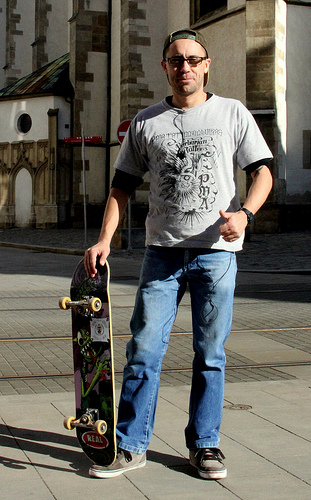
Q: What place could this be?
A: It is a street.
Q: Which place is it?
A: It is a street.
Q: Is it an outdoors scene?
A: Yes, it is outdoors.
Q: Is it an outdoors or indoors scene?
A: It is outdoors.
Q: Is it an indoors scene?
A: No, it is outdoors.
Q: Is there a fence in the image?
A: No, there are no fences.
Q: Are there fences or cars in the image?
A: No, there are no fences or cars.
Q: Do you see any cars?
A: No, there are no cars.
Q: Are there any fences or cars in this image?
A: No, there are no cars or fences.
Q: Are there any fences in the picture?
A: No, there are no fences.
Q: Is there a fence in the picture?
A: No, there are no fences.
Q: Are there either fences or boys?
A: No, there are no fences or boys.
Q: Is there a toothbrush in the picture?
A: No, there are no toothbrushes.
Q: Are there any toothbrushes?
A: No, there are no toothbrushes.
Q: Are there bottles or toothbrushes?
A: No, there are no toothbrushes or bottles.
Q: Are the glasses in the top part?
A: Yes, the glasses are in the top of the image.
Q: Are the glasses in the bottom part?
A: No, the glasses are in the top of the image.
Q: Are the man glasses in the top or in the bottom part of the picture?
A: The glasses are in the top of the image.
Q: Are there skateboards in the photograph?
A: Yes, there is a skateboard.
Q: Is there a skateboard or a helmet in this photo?
A: Yes, there is a skateboard.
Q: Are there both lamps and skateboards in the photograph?
A: No, there is a skateboard but no lamps.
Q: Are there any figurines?
A: No, there are no figurines.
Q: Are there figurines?
A: No, there are no figurines.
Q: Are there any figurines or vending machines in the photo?
A: No, there are no figurines or vending machines.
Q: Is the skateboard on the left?
A: Yes, the skateboard is on the left of the image.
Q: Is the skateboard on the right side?
A: No, the skateboard is on the left of the image.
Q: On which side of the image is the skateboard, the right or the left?
A: The skateboard is on the left of the image.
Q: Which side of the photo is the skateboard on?
A: The skateboard is on the left of the image.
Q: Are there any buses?
A: No, there are no buses.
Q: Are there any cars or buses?
A: No, there are no buses or cars.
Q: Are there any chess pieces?
A: No, there are no chess pieces.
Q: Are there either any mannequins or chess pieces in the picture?
A: No, there are no chess pieces or mannequins.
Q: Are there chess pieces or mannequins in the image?
A: No, there are no chess pieces or mannequins.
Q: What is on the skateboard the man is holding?
A: The sticker is on the skateboard.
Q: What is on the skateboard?
A: The sticker is on the skateboard.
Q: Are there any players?
A: No, there are no players.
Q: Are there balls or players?
A: No, there are no players or balls.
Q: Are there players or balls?
A: No, there are no players or balls.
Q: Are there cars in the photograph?
A: No, there are no cars.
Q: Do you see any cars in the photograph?
A: No, there are no cars.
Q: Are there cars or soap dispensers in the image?
A: No, there are no cars or soap dispensers.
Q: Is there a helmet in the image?
A: No, there are no helmets.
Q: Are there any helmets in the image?
A: No, there are no helmets.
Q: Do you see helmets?
A: No, there are no helmets.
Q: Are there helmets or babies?
A: No, there are no helmets or babies.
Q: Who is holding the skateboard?
A: The man is holding the skateboard.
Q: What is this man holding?
A: The man is holding the skateboard.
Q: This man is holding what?
A: The man is holding the skateboard.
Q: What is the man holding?
A: The man is holding the skateboard.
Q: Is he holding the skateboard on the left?
A: Yes, the man is holding the skateboard.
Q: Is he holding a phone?
A: No, the man is holding the skateboard.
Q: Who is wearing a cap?
A: The man is wearing a cap.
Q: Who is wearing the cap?
A: The man is wearing a cap.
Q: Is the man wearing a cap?
A: Yes, the man is wearing a cap.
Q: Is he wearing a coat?
A: No, the man is wearing a cap.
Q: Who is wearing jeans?
A: The man is wearing jeans.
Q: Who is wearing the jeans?
A: The man is wearing jeans.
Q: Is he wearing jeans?
A: Yes, the man is wearing jeans.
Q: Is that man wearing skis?
A: No, the man is wearing jeans.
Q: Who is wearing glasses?
A: The man is wearing glasses.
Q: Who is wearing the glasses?
A: The man is wearing glasses.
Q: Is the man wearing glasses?
A: Yes, the man is wearing glasses.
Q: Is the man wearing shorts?
A: No, the man is wearing glasses.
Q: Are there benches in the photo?
A: No, there are no benches.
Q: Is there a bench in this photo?
A: No, there are no benches.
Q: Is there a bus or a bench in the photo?
A: No, there are no benches or buses.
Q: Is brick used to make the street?
A: Yes, the street is made of brick.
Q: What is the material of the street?
A: The street is made of brick.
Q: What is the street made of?
A: The street is made of brick.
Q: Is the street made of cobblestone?
A: No, the street is made of brick.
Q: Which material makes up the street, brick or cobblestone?
A: The street is made of brick.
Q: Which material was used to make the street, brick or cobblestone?
A: The street is made of brick.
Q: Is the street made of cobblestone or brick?
A: The street is made of brick.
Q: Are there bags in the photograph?
A: No, there are no bags.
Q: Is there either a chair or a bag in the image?
A: No, there are no bags or chairs.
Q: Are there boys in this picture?
A: No, there are no boys.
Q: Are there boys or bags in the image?
A: No, there are no boys or bags.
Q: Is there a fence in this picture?
A: No, there are no fences.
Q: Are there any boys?
A: No, there are no boys.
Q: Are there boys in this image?
A: No, there are no boys.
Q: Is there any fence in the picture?
A: No, there are no fences.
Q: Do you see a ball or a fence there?
A: No, there are no fences or balls.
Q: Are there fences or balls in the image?
A: No, there are no fences or balls.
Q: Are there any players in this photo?
A: No, there are no players.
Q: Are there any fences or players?
A: No, there are no players or fences.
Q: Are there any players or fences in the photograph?
A: No, there are no players or fences.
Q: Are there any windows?
A: Yes, there is a window.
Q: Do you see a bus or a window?
A: Yes, there is a window.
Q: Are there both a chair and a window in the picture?
A: No, there is a window but no chairs.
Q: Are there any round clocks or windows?
A: Yes, there is a round window.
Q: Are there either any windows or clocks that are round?
A: Yes, the window is round.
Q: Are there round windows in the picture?
A: Yes, there is a round window.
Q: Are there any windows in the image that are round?
A: Yes, there is a window that is round.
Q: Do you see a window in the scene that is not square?
A: Yes, there is a round window.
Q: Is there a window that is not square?
A: Yes, there is a round window.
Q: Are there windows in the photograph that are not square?
A: Yes, there is a round window.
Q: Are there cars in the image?
A: No, there are no cars.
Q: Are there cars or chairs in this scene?
A: No, there are no cars or chairs.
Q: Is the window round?
A: Yes, the window is round.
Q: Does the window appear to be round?
A: Yes, the window is round.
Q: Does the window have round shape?
A: Yes, the window is round.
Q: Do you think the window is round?
A: Yes, the window is round.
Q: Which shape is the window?
A: The window is round.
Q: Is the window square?
A: No, the window is round.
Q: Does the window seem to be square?
A: No, the window is round.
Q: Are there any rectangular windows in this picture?
A: No, there is a window but it is round.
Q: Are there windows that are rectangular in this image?
A: No, there is a window but it is round.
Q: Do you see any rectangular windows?
A: No, there is a window but it is round.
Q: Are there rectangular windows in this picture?
A: No, there is a window but it is round.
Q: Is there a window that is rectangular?
A: No, there is a window but it is round.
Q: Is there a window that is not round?
A: No, there is a window but it is round.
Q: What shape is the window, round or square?
A: The window is round.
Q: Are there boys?
A: No, there are no boys.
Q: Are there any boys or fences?
A: No, there are no boys or fences.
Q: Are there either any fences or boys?
A: No, there are no boys or fences.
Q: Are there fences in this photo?
A: No, there are no fences.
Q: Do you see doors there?
A: Yes, there is a door.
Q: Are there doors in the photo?
A: Yes, there is a door.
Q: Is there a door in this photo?
A: Yes, there is a door.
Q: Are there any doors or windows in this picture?
A: Yes, there is a door.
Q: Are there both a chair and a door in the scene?
A: No, there is a door but no chairs.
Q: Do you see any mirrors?
A: No, there are no mirrors.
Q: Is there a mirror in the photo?
A: No, there are no mirrors.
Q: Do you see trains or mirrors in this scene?
A: No, there are no mirrors or trains.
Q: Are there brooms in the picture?
A: No, there are no brooms.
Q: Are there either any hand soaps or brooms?
A: No, there are no brooms or hand soaps.